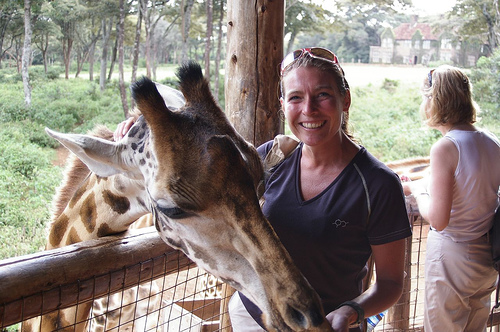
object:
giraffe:
[13, 60, 335, 331]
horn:
[128, 74, 175, 135]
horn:
[173, 61, 217, 110]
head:
[120, 61, 332, 331]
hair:
[128, 74, 156, 100]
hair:
[173, 59, 207, 87]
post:
[217, 1, 286, 331]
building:
[369, 13, 500, 66]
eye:
[150, 203, 199, 221]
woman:
[226, 46, 412, 331]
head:
[279, 46, 351, 150]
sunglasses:
[279, 46, 347, 92]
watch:
[335, 300, 365, 328]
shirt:
[237, 139, 414, 331]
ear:
[148, 79, 188, 109]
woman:
[398, 68, 498, 331]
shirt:
[429, 125, 500, 244]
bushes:
[0, 119, 60, 150]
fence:
[2, 194, 499, 331]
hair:
[276, 51, 365, 148]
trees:
[0, 1, 42, 61]